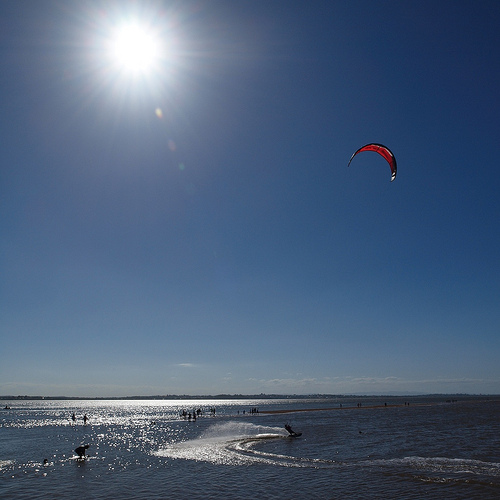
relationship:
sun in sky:
[93, 4, 178, 88] [0, 6, 497, 392]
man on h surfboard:
[279, 422, 297, 437] [279, 430, 301, 437]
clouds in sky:
[165, 358, 485, 386] [98, 183, 338, 307]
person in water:
[72, 439, 91, 459] [0, 391, 499, 498]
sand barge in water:
[206, 400, 458, 417] [0, 391, 499, 498]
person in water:
[69, 444, 117, 478] [94, 422, 269, 479]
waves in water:
[160, 462, 211, 496] [176, 413, 266, 468]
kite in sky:
[336, 138, 406, 184] [0, 0, 497, 312]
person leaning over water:
[72, 437, 89, 471] [9, 402, 493, 486]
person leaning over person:
[284, 419, 299, 447] [179, 411, 188, 418]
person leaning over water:
[66, 412, 78, 421] [9, 402, 493, 486]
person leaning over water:
[81, 412, 88, 423] [9, 402, 493, 486]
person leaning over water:
[179, 411, 188, 418] [9, 402, 493, 486]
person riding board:
[280, 417, 312, 445] [290, 428, 309, 443]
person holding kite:
[280, 417, 312, 445] [327, 134, 412, 203]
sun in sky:
[93, 4, 178, 88] [337, 77, 433, 146]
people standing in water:
[68, 410, 89, 425] [0, 391, 499, 498]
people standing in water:
[177, 402, 219, 422] [0, 391, 499, 498]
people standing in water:
[401, 395, 414, 409] [0, 391, 499, 498]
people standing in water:
[356, 400, 368, 407] [0, 391, 499, 498]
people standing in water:
[245, 402, 262, 417] [0, 391, 499, 498]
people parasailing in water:
[272, 414, 308, 457] [3, 397, 498, 494]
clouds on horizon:
[165, 358, 485, 386] [2, 336, 484, 396]